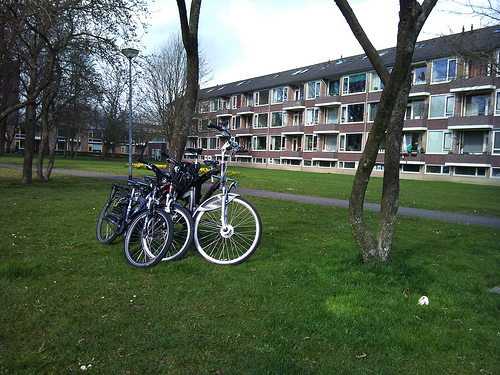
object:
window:
[340, 128, 365, 155]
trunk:
[335, 0, 442, 267]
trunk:
[170, 0, 202, 170]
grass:
[3, 157, 497, 371]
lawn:
[0, 156, 498, 373]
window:
[252, 87, 270, 106]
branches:
[23, 19, 55, 44]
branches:
[38, 5, 58, 27]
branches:
[56, 29, 109, 45]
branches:
[22, 53, 39, 76]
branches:
[53, 2, 100, 16]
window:
[450, 85, 496, 118]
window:
[410, 62, 429, 86]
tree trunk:
[335, 0, 439, 266]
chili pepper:
[122, 47, 139, 179]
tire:
[192, 193, 262, 264]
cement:
[252, 189, 499, 229]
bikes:
[149, 122, 262, 266]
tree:
[1, 0, 164, 184]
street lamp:
[120, 46, 140, 181]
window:
[429, 57, 459, 85]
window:
[426, 93, 455, 120]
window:
[427, 130, 451, 155]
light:
[120, 48, 140, 60]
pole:
[127, 58, 133, 175]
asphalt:
[0, 165, 499, 229]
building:
[166, 23, 499, 186]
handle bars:
[136, 150, 183, 176]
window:
[339, 132, 364, 153]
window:
[341, 73, 368, 95]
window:
[431, 59, 456, 81]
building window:
[341, 72, 367, 96]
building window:
[340, 102, 365, 124]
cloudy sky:
[225, 5, 328, 70]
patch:
[323, 294, 416, 330]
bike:
[95, 158, 174, 268]